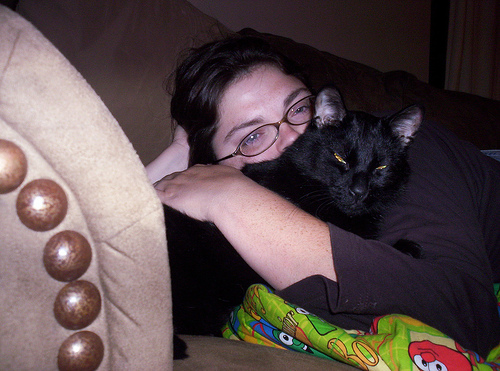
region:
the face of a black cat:
[310, 85, 425, 213]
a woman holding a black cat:
[148, 40, 498, 360]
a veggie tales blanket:
[224, 285, 498, 367]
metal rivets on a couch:
[0, 137, 107, 369]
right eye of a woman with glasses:
[234, 120, 278, 159]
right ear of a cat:
[312, 83, 345, 129]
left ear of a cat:
[380, 100, 424, 149]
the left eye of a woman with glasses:
[287, 95, 311, 128]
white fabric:
[448, 4, 496, 96]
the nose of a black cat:
[348, 175, 368, 199]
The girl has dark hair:
[158, 23, 347, 170]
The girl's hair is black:
[151, 15, 308, 162]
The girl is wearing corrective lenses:
[206, 98, 351, 160]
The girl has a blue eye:
[241, 124, 273, 152]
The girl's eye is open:
[237, 129, 282, 155]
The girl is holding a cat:
[164, 80, 450, 340]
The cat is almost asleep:
[168, 80, 438, 342]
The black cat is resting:
[160, 95, 445, 353]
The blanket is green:
[205, 237, 499, 369]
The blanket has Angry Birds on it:
[217, 255, 489, 369]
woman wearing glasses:
[154, 17, 424, 245]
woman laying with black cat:
[158, 19, 439, 302]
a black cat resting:
[160, 95, 424, 351]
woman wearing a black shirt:
[160, 17, 494, 332]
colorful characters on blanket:
[230, 287, 452, 369]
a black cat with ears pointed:
[295, 85, 427, 211]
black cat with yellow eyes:
[305, 90, 442, 206]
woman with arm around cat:
[146, 20, 456, 308]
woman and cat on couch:
[27, 26, 448, 367]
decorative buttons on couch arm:
[6, 116, 187, 369]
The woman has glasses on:
[243, 77, 368, 188]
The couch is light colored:
[81, 210, 191, 368]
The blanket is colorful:
[244, 290, 414, 369]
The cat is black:
[301, 96, 422, 238]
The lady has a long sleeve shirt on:
[298, 227, 476, 328]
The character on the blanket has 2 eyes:
[411, 335, 461, 369]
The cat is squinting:
[330, 134, 396, 197]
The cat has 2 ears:
[291, 70, 439, 179]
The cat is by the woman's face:
[211, 84, 345, 211]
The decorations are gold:
[4, 167, 134, 344]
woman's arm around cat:
[139, 158, 295, 319]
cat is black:
[240, 125, 447, 221]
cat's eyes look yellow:
[331, 138, 404, 184]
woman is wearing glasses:
[185, 113, 333, 180]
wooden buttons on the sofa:
[3, 167, 145, 367]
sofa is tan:
[39, 102, 174, 349]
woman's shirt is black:
[384, 213, 489, 298]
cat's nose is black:
[333, 185, 385, 218]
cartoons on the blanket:
[260, 307, 454, 369]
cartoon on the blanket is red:
[413, 332, 455, 369]